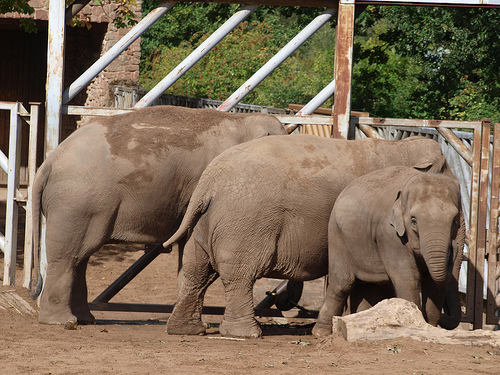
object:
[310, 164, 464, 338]
elephant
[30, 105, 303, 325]
elephant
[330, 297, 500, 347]
log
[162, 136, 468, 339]
elephants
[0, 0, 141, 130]
wall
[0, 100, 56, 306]
fence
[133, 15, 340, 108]
trees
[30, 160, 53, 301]
tail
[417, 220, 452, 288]
trunk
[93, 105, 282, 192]
dirt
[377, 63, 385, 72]
leaves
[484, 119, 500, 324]
gate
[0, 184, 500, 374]
ground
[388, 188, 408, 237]
ear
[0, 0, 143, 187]
building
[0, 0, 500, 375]
enclosure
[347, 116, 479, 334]
fence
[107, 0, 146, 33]
lantern